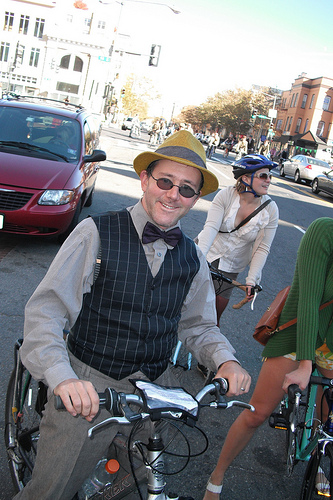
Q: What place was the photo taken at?
A: It was taken at the road.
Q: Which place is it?
A: It is a road.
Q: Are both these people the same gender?
A: No, they are both male and female.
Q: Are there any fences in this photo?
A: No, there are no fences.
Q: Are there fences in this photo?
A: No, there are no fences.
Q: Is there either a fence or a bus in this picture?
A: No, there are no fences or buses.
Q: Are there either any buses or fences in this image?
A: No, there are no fences or buses.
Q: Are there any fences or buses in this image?
A: No, there are no fences or buses.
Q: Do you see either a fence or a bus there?
A: No, there are no fences or buses.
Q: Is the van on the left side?
A: Yes, the van is on the left of the image.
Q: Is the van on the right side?
A: No, the van is on the left of the image.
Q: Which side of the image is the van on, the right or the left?
A: The van is on the left of the image.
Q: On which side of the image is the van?
A: The van is on the left of the image.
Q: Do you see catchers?
A: No, there are no catchers.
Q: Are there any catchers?
A: No, there are no catchers.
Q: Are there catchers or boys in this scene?
A: No, there are no catchers or boys.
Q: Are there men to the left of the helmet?
A: Yes, there is a man to the left of the helmet.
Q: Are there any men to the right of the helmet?
A: No, the man is to the left of the helmet.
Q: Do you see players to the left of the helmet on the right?
A: No, there is a man to the left of the helmet.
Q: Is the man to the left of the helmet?
A: Yes, the man is to the left of the helmet.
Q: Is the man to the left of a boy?
A: No, the man is to the left of the helmet.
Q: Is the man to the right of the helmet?
A: No, the man is to the left of the helmet.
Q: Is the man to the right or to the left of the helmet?
A: The man is to the left of the helmet.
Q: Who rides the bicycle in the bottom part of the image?
A: The man rides the bicycle.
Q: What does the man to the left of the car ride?
A: The man rides the bicycle.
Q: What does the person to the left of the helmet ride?
A: The man rides the bicycle.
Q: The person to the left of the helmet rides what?
A: The man rides the bicycle.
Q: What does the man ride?
A: The man rides the bicycle.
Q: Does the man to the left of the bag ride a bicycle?
A: Yes, the man rides a bicycle.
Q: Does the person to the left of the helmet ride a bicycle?
A: Yes, the man rides a bicycle.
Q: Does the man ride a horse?
A: No, the man rides a bicycle.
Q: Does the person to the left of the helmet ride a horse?
A: No, the man rides a bicycle.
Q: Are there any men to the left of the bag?
A: Yes, there is a man to the left of the bag.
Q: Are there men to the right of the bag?
A: No, the man is to the left of the bag.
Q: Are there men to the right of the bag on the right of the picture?
A: No, the man is to the left of the bag.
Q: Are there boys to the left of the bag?
A: No, there is a man to the left of the bag.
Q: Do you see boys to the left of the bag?
A: No, there is a man to the left of the bag.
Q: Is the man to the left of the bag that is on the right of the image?
A: Yes, the man is to the left of the bag.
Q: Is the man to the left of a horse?
A: No, the man is to the left of the bag.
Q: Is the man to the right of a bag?
A: No, the man is to the left of a bag.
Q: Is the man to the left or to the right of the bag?
A: The man is to the left of the bag.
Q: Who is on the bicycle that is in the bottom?
A: The man is on the bicycle.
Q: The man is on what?
A: The man is on the bicycle.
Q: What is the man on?
A: The man is on the bicycle.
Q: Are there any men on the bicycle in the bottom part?
A: Yes, there is a man on the bicycle.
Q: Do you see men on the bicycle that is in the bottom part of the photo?
A: Yes, there is a man on the bicycle.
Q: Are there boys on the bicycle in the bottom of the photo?
A: No, there is a man on the bicycle.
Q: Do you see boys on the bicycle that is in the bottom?
A: No, there is a man on the bicycle.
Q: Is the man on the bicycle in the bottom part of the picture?
A: Yes, the man is on the bicycle.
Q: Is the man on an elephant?
A: No, the man is on the bicycle.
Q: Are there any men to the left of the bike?
A: Yes, there is a man to the left of the bike.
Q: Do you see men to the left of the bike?
A: Yes, there is a man to the left of the bike.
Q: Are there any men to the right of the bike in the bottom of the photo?
A: No, the man is to the left of the bike.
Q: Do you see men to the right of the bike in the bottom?
A: No, the man is to the left of the bike.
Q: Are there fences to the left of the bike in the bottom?
A: No, there is a man to the left of the bike.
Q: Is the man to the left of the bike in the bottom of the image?
A: Yes, the man is to the left of the bike.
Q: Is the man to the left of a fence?
A: No, the man is to the left of the bike.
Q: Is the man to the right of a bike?
A: No, the man is to the left of a bike.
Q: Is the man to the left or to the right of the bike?
A: The man is to the left of the bike.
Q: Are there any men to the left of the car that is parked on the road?
A: Yes, there is a man to the left of the car.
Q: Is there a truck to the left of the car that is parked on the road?
A: No, there is a man to the left of the car.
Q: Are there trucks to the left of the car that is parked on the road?
A: No, there is a man to the left of the car.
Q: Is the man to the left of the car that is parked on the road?
A: Yes, the man is to the left of the car.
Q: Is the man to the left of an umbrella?
A: No, the man is to the left of the car.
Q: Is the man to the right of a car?
A: No, the man is to the left of a car.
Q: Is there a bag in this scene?
A: Yes, there is a bag.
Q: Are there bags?
A: Yes, there is a bag.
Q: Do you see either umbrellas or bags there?
A: Yes, there is a bag.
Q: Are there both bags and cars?
A: Yes, there are both a bag and a car.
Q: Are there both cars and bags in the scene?
A: Yes, there are both a bag and a car.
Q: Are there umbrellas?
A: No, there are no umbrellas.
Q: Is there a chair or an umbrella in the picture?
A: No, there are no umbrellas or chairs.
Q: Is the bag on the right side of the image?
A: Yes, the bag is on the right of the image.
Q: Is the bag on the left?
A: No, the bag is on the right of the image.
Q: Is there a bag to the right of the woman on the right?
A: Yes, there is a bag to the right of the woman.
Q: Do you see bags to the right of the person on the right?
A: Yes, there is a bag to the right of the woman.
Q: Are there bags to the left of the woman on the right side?
A: No, the bag is to the right of the woman.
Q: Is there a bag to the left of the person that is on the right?
A: No, the bag is to the right of the woman.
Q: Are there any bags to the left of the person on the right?
A: No, the bag is to the right of the woman.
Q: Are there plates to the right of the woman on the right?
A: No, there is a bag to the right of the woman.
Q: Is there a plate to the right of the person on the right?
A: No, there is a bag to the right of the woman.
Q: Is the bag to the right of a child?
A: No, the bag is to the right of the woman.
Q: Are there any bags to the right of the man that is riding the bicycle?
A: Yes, there is a bag to the right of the man.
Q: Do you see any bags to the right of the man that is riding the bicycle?
A: Yes, there is a bag to the right of the man.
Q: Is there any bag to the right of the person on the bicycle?
A: Yes, there is a bag to the right of the man.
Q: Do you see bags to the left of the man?
A: No, the bag is to the right of the man.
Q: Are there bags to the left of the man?
A: No, the bag is to the right of the man.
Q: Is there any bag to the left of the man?
A: No, the bag is to the right of the man.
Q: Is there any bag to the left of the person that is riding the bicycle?
A: No, the bag is to the right of the man.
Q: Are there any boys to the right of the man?
A: No, there is a bag to the right of the man.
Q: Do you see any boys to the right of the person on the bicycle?
A: No, there is a bag to the right of the man.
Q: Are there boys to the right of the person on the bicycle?
A: No, there is a bag to the right of the man.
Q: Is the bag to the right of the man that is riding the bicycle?
A: Yes, the bag is to the right of the man.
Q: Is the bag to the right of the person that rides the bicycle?
A: Yes, the bag is to the right of the man.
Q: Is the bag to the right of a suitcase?
A: No, the bag is to the right of the man.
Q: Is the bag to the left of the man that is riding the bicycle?
A: No, the bag is to the right of the man.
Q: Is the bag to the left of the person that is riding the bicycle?
A: No, the bag is to the right of the man.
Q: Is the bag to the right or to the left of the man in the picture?
A: The bag is to the right of the man.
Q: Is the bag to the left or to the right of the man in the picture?
A: The bag is to the right of the man.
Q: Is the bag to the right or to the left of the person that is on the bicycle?
A: The bag is to the right of the man.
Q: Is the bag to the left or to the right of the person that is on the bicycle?
A: The bag is to the right of the man.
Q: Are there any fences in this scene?
A: No, there are no fences.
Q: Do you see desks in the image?
A: No, there are no desks.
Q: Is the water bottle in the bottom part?
A: Yes, the water bottle is in the bottom of the image.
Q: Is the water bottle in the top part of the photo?
A: No, the water bottle is in the bottom of the image.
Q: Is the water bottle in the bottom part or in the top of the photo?
A: The water bottle is in the bottom of the image.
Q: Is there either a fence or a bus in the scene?
A: No, there are no fences or buses.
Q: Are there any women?
A: Yes, there is a woman.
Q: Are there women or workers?
A: Yes, there is a woman.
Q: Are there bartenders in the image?
A: No, there are no bartenders.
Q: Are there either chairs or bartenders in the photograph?
A: No, there are no bartenders or chairs.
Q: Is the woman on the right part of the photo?
A: Yes, the woman is on the right of the image.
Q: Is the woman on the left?
A: No, the woman is on the right of the image.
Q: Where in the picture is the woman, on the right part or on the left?
A: The woman is on the right of the image.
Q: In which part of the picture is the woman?
A: The woman is on the right of the image.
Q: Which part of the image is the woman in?
A: The woman is on the right of the image.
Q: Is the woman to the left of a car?
A: Yes, the woman is to the left of a car.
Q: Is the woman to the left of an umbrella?
A: No, the woman is to the left of a car.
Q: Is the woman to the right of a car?
A: No, the woman is to the left of a car.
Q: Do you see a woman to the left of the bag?
A: Yes, there is a woman to the left of the bag.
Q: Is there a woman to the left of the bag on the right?
A: Yes, there is a woman to the left of the bag.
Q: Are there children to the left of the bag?
A: No, there is a woman to the left of the bag.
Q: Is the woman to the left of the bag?
A: Yes, the woman is to the left of the bag.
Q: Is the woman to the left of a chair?
A: No, the woman is to the left of the bag.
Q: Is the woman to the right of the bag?
A: No, the woman is to the left of the bag.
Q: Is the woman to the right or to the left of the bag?
A: The woman is to the left of the bag.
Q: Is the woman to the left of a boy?
A: No, the woman is to the left of the car.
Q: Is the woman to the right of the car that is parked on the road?
A: No, the woman is to the left of the car.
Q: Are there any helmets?
A: Yes, there is a helmet.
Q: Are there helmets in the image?
A: Yes, there is a helmet.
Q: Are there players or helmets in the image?
A: Yes, there is a helmet.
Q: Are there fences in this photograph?
A: No, there are no fences.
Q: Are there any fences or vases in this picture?
A: No, there are no fences or vases.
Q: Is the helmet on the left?
A: No, the helmet is on the right of the image.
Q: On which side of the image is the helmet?
A: The helmet is on the right of the image.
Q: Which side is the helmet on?
A: The helmet is on the right of the image.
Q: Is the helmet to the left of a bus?
A: No, the helmet is to the left of the car.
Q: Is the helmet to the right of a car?
A: No, the helmet is to the left of a car.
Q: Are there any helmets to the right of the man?
A: Yes, there is a helmet to the right of the man.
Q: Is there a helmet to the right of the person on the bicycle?
A: Yes, there is a helmet to the right of the man.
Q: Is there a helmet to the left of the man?
A: No, the helmet is to the right of the man.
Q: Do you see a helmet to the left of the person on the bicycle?
A: No, the helmet is to the right of the man.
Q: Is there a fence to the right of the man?
A: No, there is a helmet to the right of the man.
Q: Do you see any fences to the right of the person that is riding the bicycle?
A: No, there is a helmet to the right of the man.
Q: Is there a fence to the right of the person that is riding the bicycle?
A: No, there is a helmet to the right of the man.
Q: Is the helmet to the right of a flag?
A: No, the helmet is to the right of a man.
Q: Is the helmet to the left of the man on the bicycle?
A: No, the helmet is to the right of the man.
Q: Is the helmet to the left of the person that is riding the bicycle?
A: No, the helmet is to the right of the man.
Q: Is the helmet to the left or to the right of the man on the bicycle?
A: The helmet is to the right of the man.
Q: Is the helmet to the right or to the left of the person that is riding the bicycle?
A: The helmet is to the right of the man.